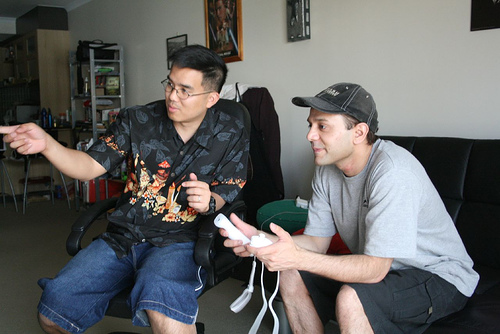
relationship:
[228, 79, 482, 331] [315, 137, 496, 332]
man sitting on couch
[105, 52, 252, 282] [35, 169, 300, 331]
man sitting on chair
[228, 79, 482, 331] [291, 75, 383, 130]
man wearing hat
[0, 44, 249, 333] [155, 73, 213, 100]
man wearing glasses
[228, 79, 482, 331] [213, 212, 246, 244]
man holding controller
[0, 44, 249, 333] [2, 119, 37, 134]
man pointing h finger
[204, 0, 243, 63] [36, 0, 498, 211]
picture hanging on wall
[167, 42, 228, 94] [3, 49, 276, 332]
hair on man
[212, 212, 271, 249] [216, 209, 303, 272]
controller in hand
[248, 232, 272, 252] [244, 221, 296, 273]
game controller in hand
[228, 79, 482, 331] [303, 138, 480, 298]
man on gray shirt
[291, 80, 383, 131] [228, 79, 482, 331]
cap on man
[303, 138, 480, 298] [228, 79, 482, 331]
gray shirt on man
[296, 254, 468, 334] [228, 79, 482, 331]
shorts on man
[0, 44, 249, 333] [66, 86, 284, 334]
man on chair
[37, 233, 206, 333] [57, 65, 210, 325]
jean shorts on man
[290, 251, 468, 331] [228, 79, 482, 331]
shorts on man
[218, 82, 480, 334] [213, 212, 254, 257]
man holding controller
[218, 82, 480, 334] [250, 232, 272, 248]
man holding game controller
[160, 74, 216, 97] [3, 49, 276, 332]
glasses on man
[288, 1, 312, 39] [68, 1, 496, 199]
picture on wall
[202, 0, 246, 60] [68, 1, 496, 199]
picture on wall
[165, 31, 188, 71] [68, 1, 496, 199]
picture on wall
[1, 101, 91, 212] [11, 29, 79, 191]
table near bookshelf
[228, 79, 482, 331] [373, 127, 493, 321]
man sitting on couch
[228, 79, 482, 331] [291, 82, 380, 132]
man wearing cap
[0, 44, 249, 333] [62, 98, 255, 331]
man sitting in chair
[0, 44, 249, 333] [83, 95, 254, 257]
man wearing shirt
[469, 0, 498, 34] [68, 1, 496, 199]
picture on wall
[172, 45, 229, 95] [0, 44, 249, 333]
hair on man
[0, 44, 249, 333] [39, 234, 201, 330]
man wearing jean shorts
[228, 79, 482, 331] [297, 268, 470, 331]
man wearing shorts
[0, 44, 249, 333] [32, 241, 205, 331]
man wearing shorts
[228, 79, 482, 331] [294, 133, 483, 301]
man wearing gray shirt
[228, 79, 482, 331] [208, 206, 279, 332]
man wearing wii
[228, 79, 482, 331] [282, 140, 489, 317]
man wearing shirt